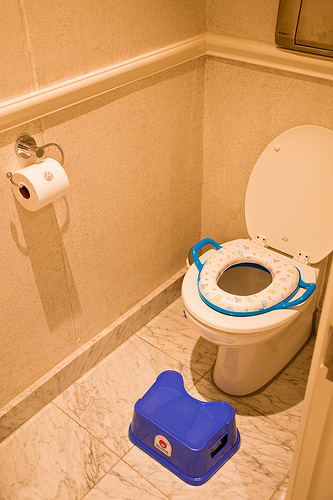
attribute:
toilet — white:
[171, 161, 296, 387]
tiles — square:
[2, 265, 331, 497]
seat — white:
[195, 234, 314, 316]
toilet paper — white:
[8, 161, 72, 208]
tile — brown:
[51, 386, 152, 496]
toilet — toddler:
[153, 135, 328, 354]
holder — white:
[274, 0, 332, 62]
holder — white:
[24, 140, 93, 215]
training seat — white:
[191, 235, 316, 315]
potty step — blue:
[126, 361, 250, 491]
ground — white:
[262, 87, 292, 127]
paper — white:
[12, 156, 71, 213]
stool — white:
[126, 370, 240, 485]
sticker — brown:
[151, 434, 174, 456]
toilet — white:
[182, 120, 330, 393]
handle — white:
[205, 433, 234, 452]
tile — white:
[1, 337, 155, 494]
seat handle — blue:
[192, 237, 221, 272]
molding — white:
[62, 70, 165, 83]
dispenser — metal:
[16, 128, 76, 187]